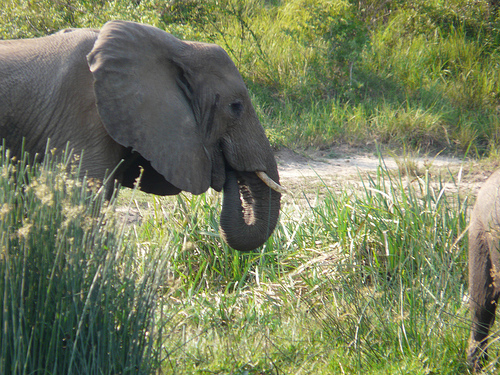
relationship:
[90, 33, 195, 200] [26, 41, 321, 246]
ears on elephant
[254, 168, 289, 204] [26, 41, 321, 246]
tusks on elephant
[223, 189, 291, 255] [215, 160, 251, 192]
trunk by mouth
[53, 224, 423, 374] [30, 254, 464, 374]
grass on ground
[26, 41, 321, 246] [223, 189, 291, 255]
elephant has trunk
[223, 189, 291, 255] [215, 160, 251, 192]
trunk in mouth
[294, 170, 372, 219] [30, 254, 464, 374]
dirt on ground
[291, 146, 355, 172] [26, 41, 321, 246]
twig behind elephant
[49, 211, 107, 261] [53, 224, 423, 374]
buds on grass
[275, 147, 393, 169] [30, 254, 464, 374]
sand on ground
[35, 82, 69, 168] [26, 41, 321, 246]
lines on elephant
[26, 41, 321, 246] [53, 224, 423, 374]
elephant eating grass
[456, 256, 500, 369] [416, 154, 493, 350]
leg on elephant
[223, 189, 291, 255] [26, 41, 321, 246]
trunk on elephant